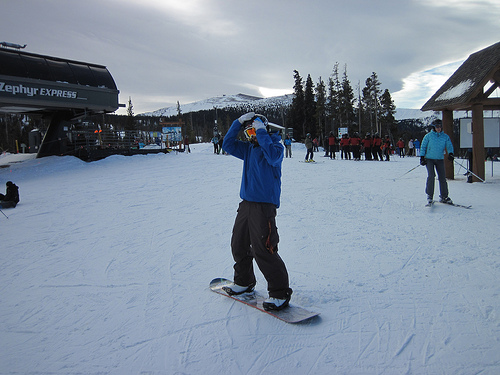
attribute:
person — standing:
[225, 110, 291, 307]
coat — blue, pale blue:
[223, 124, 282, 204]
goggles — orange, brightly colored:
[243, 126, 258, 141]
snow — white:
[1, 133, 499, 375]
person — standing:
[327, 132, 337, 160]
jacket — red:
[337, 137, 352, 150]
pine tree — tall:
[288, 68, 303, 140]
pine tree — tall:
[305, 74, 315, 138]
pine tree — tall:
[366, 74, 380, 138]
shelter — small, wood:
[421, 43, 500, 183]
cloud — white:
[90, 0, 359, 58]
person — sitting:
[3, 177, 19, 208]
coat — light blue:
[421, 130, 452, 163]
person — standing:
[351, 131, 358, 161]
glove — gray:
[252, 119, 266, 132]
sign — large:
[160, 126, 181, 146]